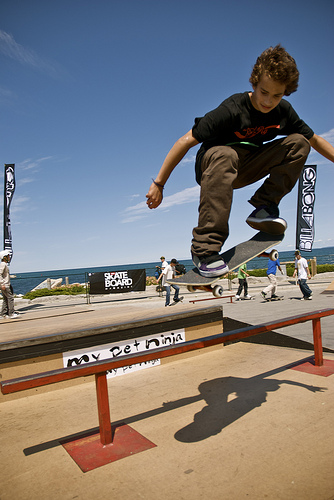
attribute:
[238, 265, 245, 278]
shirt — green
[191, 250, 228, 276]
shoe — purple, white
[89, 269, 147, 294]
sign — black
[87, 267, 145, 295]
banner — black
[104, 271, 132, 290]
lettering — white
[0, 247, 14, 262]
helmet — white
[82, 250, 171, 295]
letters — white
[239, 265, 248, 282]
shirt — green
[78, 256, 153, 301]
banner — black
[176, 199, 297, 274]
sneakers — purple, grey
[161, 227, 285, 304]
skateboard — wooden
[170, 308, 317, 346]
rail — red, black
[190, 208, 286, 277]
shoes — purple, white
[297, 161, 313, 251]
flag — black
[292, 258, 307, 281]
t-shirt — white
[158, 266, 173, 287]
t-shirt — white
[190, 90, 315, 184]
black tshirt — blue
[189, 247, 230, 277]
shoe — purple, gray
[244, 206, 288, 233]
shoe — purple, gray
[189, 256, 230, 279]
shoe — purple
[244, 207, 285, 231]
shoe — purple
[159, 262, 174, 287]
shirt — white